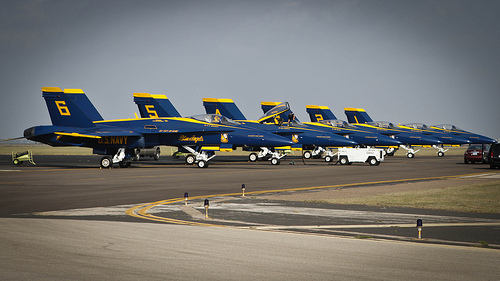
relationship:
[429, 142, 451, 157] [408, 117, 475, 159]
landing gear in plane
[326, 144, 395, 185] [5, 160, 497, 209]
car on tarmac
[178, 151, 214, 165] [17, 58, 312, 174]
landing gear of a plane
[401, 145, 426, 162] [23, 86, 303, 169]
landing gear of jet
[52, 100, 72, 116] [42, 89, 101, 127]
number on tail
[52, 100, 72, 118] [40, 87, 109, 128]
number on tail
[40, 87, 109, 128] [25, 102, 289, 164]
tail of plane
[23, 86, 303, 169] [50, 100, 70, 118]
jet have numbers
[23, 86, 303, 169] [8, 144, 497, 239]
jet on tarmac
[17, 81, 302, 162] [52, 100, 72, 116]
jet with number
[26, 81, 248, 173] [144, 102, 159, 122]
jet with 5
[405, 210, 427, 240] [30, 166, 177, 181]
light on tarmac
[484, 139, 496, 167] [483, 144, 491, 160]
suv with door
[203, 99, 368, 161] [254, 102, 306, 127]
jet with cockpit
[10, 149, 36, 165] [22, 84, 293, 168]
item used to service jet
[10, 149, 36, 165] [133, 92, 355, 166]
item used to service jet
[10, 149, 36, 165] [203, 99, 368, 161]
item used to service jet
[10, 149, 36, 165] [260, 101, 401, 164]
item used to service jet